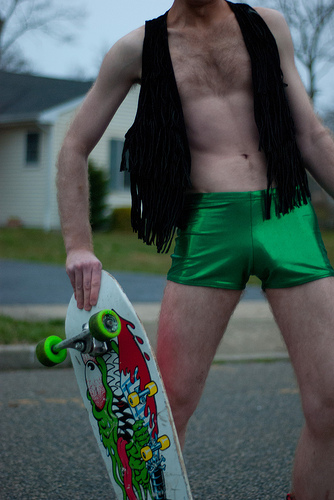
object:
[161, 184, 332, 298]
shorts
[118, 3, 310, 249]
vest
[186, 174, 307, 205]
fringe